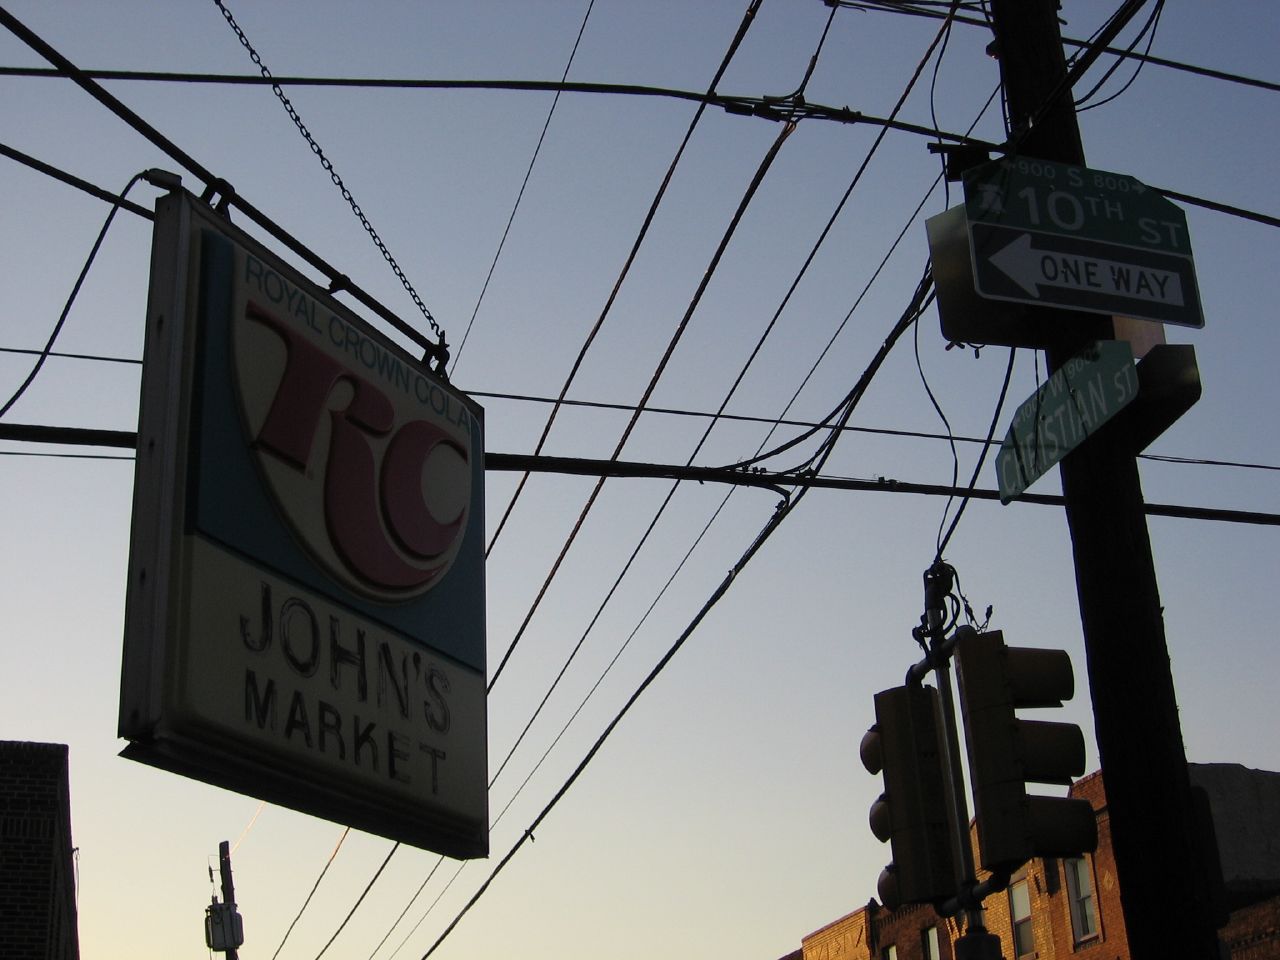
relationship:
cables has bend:
[680, 389, 853, 582] [742, 389, 858, 477]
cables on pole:
[229, 100, 862, 584] [990, 407, 1229, 909]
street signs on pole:
[932, 190, 1222, 511] [1060, 484, 1197, 912]